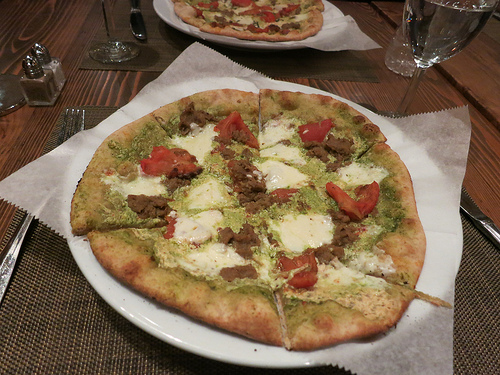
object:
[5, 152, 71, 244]
paper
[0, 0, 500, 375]
table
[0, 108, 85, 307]
fork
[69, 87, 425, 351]
pizza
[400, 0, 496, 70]
water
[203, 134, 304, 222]
hamburger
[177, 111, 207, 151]
cheese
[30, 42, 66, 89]
salt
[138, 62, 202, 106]
paper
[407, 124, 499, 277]
knife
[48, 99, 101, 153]
top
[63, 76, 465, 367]
plate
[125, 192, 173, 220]
sausage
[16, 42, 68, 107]
shakers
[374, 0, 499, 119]
bottle